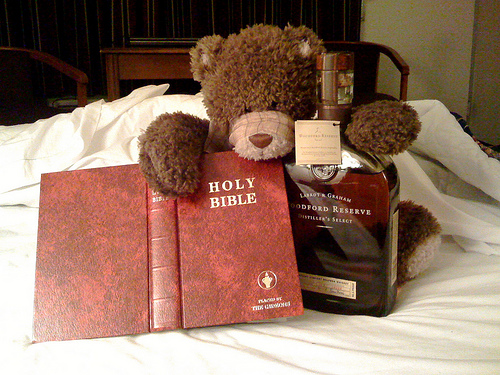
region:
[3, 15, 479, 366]
alcohol, bible and beer on a bed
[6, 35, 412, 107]
a wooden table and two chairs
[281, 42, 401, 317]
a large bottle of dark alcohol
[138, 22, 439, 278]
brown teddy bear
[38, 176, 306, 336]
red bible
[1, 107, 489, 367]
white sheets on the bed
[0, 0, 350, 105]
dark curtains behind the table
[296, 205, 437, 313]
part of the teddy bear is visible through the alcohol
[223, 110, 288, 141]
teddy bear's nose looks plaid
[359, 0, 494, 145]
beige walls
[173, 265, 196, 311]
aprt of a line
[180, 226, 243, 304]
part of a cobver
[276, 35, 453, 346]
a bottle of bourbon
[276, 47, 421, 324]
a bottle of whisky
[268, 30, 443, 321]
a nice bottle of whiskey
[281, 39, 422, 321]
a nice bottle of bourbon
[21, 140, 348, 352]
a hardcover bible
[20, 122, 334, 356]
a Gideon Bible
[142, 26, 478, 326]
a brown teddy bear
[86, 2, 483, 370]
the bear is holding the liquor and bible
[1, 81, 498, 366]
a white sheet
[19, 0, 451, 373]
the bear is on a bed sheet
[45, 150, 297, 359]
bear holding a bible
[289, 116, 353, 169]
tag on a liquor bottle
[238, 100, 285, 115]
black eyes on a teddy bear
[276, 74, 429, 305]
bear holding a liquor bottle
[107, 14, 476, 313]
teddy bear sitting on a bed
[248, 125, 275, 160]
bear with a brown nose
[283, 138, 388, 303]
bottle liquor on a bed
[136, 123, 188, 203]
bear paw on a bible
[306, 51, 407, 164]
bear paw on a liquor bottle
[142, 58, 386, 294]
bear sitting on white sheet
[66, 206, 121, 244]
The cover of a book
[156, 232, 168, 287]
The back bone of a book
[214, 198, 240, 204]
Words embossed on the cover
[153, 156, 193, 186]
The paw of a teddy bear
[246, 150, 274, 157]
Mouth of teddy bear on the book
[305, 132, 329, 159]
A label on the bottle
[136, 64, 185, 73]
A wooden table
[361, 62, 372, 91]
A chair next to the table